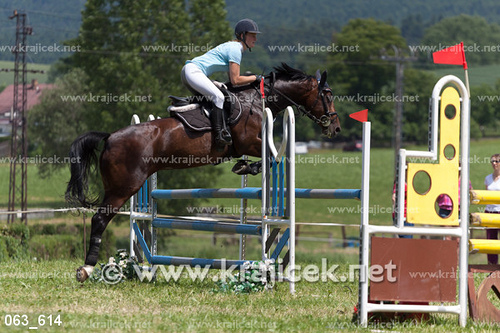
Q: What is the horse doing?
A: Jumping.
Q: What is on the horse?
A: A rider.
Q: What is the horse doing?
A: Jumping.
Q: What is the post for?
A: For the horse to jump.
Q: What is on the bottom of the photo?
A: Copywrite watermark.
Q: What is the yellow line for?
A: Gate for horse jumping.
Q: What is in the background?
A: Power line.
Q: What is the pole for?
A: For horse to jump.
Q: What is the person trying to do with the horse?
A: Jumping.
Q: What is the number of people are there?
A: One.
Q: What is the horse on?
A: A rail.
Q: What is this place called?
A: Horse racer.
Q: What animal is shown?
A: HOrse.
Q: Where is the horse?
A: On a track.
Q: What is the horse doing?
A: Jumping.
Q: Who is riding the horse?
A: A jockey.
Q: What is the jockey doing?
A: Riding the horse.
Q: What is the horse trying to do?
A: Jump.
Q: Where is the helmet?
A: ON the jockey.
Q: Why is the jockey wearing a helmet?
A: Safety.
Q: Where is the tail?
A: ON the horse.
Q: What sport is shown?
A: Equestrian riding.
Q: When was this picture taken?
A: As the horse was jumping.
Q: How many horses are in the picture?
A: One.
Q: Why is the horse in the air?
A: Its jumping over the rail.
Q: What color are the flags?
A: Red.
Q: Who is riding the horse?
A: The girl in the blue shirt.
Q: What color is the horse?
A: Dark brown.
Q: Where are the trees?
A: Behind the horse.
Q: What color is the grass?
A: Green.